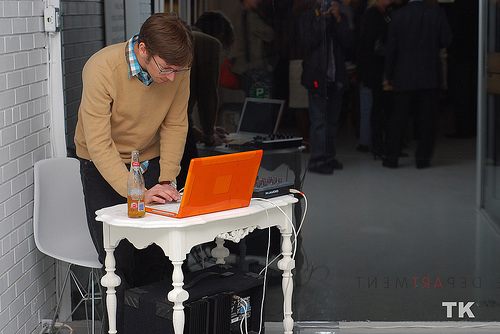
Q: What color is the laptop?
A: Orange.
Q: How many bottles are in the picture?
A: One.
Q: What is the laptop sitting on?
A: A table.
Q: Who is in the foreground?
A: A man.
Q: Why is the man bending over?
A: He is using the laptop.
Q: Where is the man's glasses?
A: On his face.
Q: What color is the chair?
A: Gray.